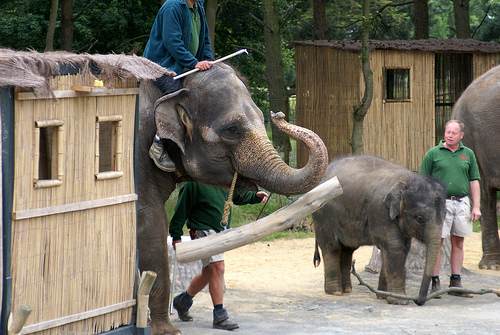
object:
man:
[410, 117, 484, 297]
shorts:
[440, 197, 474, 239]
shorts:
[193, 230, 225, 267]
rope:
[221, 169, 237, 229]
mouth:
[231, 170, 262, 192]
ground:
[135, 225, 500, 335]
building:
[285, 35, 497, 194]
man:
[169, 181, 268, 328]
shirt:
[169, 177, 261, 242]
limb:
[323, 242, 344, 296]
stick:
[158, 42, 256, 80]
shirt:
[419, 141, 483, 199]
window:
[31, 123, 66, 185]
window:
[96, 117, 122, 180]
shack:
[0, 49, 163, 335]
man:
[141, 0, 211, 176]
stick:
[347, 258, 499, 308]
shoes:
[211, 314, 242, 332]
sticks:
[169, 168, 344, 273]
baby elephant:
[315, 155, 446, 305]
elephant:
[445, 62, 500, 271]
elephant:
[130, 62, 329, 333]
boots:
[448, 276, 471, 298]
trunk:
[413, 229, 439, 307]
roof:
[289, 35, 498, 53]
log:
[172, 176, 340, 263]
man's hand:
[255, 190, 269, 204]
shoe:
[427, 273, 445, 300]